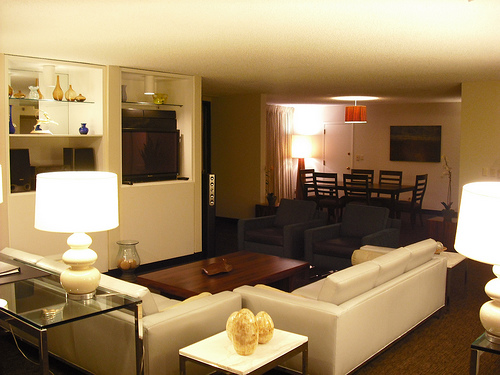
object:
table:
[137, 250, 309, 301]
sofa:
[232, 237, 447, 374]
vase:
[114, 239, 141, 274]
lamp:
[33, 170, 121, 300]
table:
[0, 252, 147, 375]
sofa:
[0, 246, 243, 374]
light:
[344, 99, 367, 124]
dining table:
[303, 179, 416, 193]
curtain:
[266, 104, 300, 204]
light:
[290, 133, 317, 198]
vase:
[78, 123, 89, 135]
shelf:
[10, 133, 103, 138]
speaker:
[201, 174, 217, 261]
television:
[121, 127, 190, 185]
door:
[323, 123, 355, 199]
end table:
[178, 328, 310, 374]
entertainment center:
[122, 107, 190, 185]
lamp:
[453, 181, 498, 345]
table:
[468, 330, 500, 374]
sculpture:
[225, 307, 260, 355]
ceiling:
[268, 52, 462, 103]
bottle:
[8, 104, 18, 134]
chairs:
[342, 173, 371, 211]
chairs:
[397, 173, 429, 227]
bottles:
[52, 75, 65, 101]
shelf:
[7, 97, 96, 105]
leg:
[134, 302, 146, 375]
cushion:
[317, 260, 381, 307]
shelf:
[120, 179, 195, 188]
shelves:
[11, 185, 104, 196]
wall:
[0, 53, 202, 276]